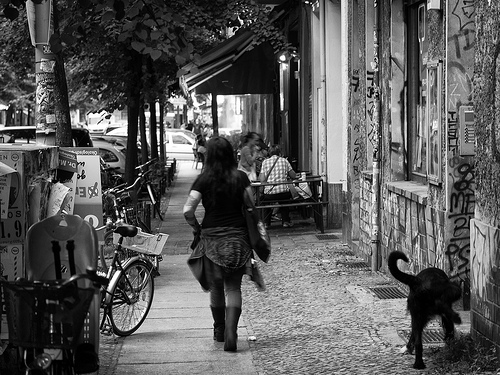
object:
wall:
[471, 0, 500, 360]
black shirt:
[190, 167, 252, 228]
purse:
[244, 196, 272, 264]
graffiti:
[448, 112, 459, 156]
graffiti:
[351, 147, 361, 163]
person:
[255, 150, 296, 229]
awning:
[175, 8, 280, 95]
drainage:
[369, 285, 407, 301]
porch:
[107, 144, 259, 375]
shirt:
[259, 155, 293, 195]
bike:
[89, 218, 161, 337]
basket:
[112, 221, 170, 256]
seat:
[24, 214, 101, 356]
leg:
[410, 314, 428, 356]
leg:
[441, 312, 454, 340]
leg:
[406, 326, 415, 349]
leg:
[441, 322, 450, 341]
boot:
[224, 306, 240, 352]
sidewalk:
[107, 152, 261, 375]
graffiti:
[446, 0, 477, 59]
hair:
[197, 136, 239, 201]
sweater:
[188, 227, 267, 294]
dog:
[381, 248, 468, 362]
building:
[340, 1, 499, 361]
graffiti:
[445, 162, 475, 279]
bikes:
[5, 212, 112, 375]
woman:
[182, 137, 257, 351]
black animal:
[388, 250, 463, 369]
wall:
[303, 14, 480, 344]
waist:
[200, 207, 251, 231]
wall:
[348, 0, 473, 310]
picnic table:
[250, 178, 325, 234]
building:
[241, 0, 342, 230]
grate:
[315, 234, 339, 240]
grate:
[344, 258, 369, 268]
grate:
[397, 329, 447, 343]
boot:
[209, 306, 226, 342]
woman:
[257, 146, 297, 230]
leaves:
[131, 5, 170, 61]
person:
[237, 131, 257, 208]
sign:
[45, 180, 73, 218]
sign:
[57, 149, 78, 173]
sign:
[58, 146, 106, 245]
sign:
[0, 160, 23, 219]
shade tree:
[80, 2, 196, 180]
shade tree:
[0, 0, 182, 110]